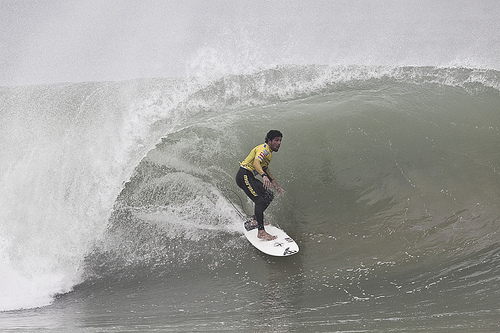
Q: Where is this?
A: This is at the ocean.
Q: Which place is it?
A: It is an ocean.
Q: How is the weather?
A: It is overcast.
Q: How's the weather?
A: It is overcast.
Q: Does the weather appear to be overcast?
A: Yes, it is overcast.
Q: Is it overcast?
A: Yes, it is overcast.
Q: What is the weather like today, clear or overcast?
A: It is overcast.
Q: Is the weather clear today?
A: No, it is overcast.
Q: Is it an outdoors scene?
A: Yes, it is outdoors.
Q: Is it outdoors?
A: Yes, it is outdoors.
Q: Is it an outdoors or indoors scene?
A: It is outdoors.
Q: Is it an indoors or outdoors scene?
A: It is outdoors.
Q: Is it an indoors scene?
A: No, it is outdoors.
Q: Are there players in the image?
A: No, there are no players.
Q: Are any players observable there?
A: No, there are no players.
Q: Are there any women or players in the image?
A: No, there are no players or women.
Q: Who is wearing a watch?
A: The man is wearing a watch.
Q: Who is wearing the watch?
A: The man is wearing a watch.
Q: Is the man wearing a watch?
A: Yes, the man is wearing a watch.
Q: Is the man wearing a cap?
A: No, the man is wearing a watch.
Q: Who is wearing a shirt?
A: The man is wearing a shirt.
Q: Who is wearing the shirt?
A: The man is wearing a shirt.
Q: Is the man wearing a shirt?
A: Yes, the man is wearing a shirt.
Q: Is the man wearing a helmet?
A: No, the man is wearing a shirt.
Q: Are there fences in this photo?
A: No, there are no fences.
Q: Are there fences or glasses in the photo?
A: No, there are no fences or glasses.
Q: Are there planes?
A: No, there are no planes.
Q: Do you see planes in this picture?
A: No, there are no planes.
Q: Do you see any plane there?
A: No, there are no airplanes.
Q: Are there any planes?
A: No, there are no planes.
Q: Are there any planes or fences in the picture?
A: No, there are no planes or fences.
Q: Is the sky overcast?
A: Yes, the sky is overcast.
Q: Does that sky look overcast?
A: Yes, the sky is overcast.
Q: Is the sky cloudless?
A: No, the sky is overcast.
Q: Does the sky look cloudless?
A: No, the sky is overcast.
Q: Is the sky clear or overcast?
A: The sky is overcast.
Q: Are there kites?
A: No, there are no kites.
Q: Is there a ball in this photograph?
A: No, there are no balls.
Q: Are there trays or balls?
A: No, there are no balls or trays.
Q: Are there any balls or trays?
A: No, there are no balls or trays.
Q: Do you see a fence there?
A: No, there are no fences.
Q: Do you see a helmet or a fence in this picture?
A: No, there are no fences or helmets.